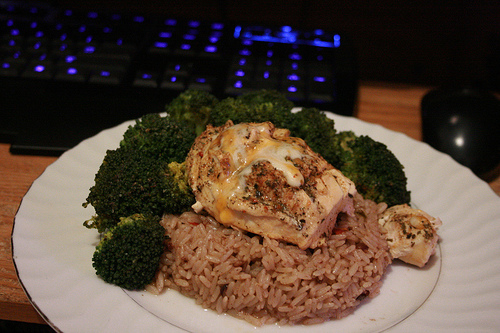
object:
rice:
[143, 185, 394, 329]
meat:
[178, 119, 360, 252]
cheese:
[207, 124, 310, 227]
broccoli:
[89, 210, 174, 293]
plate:
[6, 97, 500, 333]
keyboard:
[0, 0, 349, 102]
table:
[0, 0, 500, 333]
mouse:
[415, 85, 500, 186]